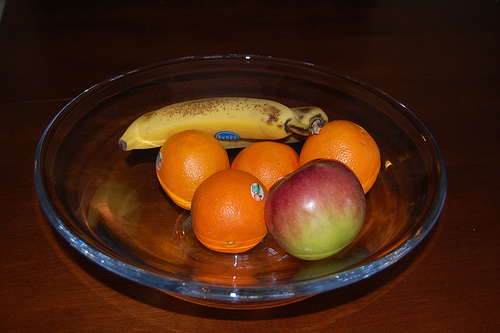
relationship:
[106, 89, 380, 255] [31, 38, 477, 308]
fruit inside of plate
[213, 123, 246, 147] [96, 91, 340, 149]
sticker on top of banana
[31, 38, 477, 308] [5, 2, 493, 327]
plate on top of surface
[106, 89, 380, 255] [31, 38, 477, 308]
fruit on top of plate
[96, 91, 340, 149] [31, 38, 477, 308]
banana on top of plate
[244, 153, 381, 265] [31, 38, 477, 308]
apple on top of plate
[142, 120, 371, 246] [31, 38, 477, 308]
oranges are on top of plate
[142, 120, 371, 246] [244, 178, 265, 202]
oranges have sticker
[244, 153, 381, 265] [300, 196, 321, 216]
apple has glare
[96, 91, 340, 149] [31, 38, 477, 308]
banana inside of plate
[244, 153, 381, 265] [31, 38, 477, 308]
apple inside of plate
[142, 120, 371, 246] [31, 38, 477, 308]
oranges are inside of plate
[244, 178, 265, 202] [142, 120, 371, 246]
sticker on top of oranges